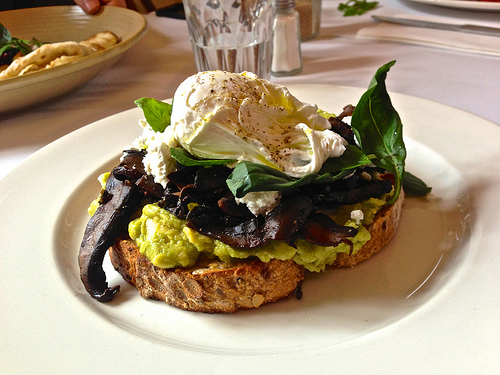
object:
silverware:
[369, 14, 500, 39]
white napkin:
[354, 22, 500, 58]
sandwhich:
[76, 69, 433, 317]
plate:
[0, 83, 499, 374]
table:
[6, 111, 82, 129]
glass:
[184, 0, 274, 28]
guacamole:
[144, 220, 182, 255]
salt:
[270, 0, 304, 77]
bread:
[107, 185, 404, 315]